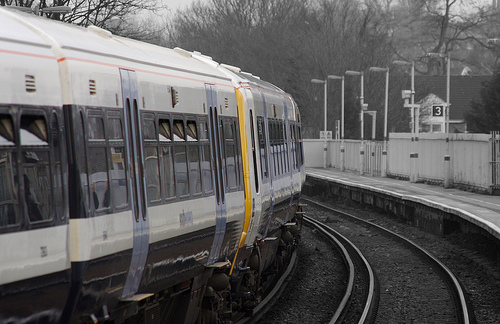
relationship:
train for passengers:
[7, 13, 306, 280] [182, 164, 219, 194]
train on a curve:
[7, 13, 306, 280] [248, 230, 309, 310]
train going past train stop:
[7, 13, 306, 280] [320, 68, 499, 217]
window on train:
[158, 117, 180, 202] [7, 13, 306, 280]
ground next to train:
[266, 228, 339, 324] [7, 13, 306, 280]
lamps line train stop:
[311, 51, 465, 130] [320, 68, 499, 217]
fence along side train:
[309, 137, 491, 190] [7, 13, 306, 280]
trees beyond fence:
[249, 3, 473, 111] [309, 137, 491, 190]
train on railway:
[7, 13, 306, 280] [308, 195, 499, 323]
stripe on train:
[232, 83, 251, 277] [7, 13, 306, 280]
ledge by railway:
[322, 174, 443, 229] [308, 195, 499, 323]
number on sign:
[435, 106, 446, 118] [426, 101, 452, 131]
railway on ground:
[308, 195, 499, 323] [266, 228, 339, 324]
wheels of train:
[207, 272, 275, 323] [7, 13, 306, 280]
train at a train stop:
[7, 13, 306, 280] [320, 68, 499, 217]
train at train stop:
[7, 13, 306, 280] [320, 68, 499, 217]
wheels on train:
[207, 272, 275, 323] [7, 13, 306, 280]